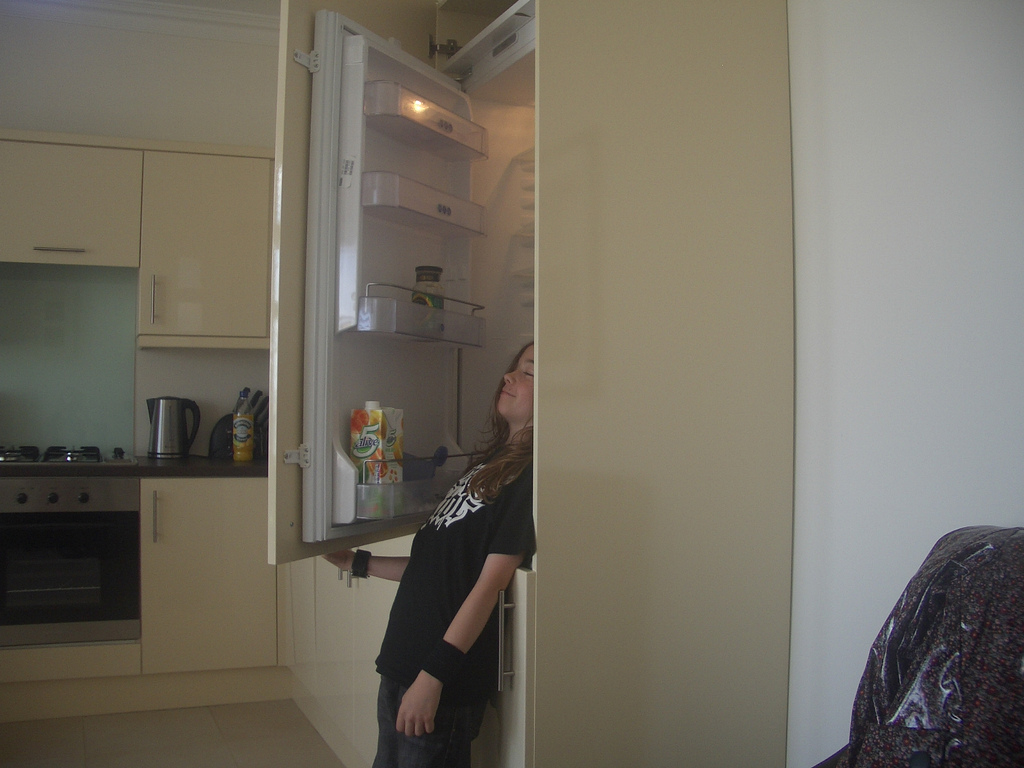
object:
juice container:
[350, 401, 405, 519]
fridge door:
[266, 0, 493, 565]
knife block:
[208, 388, 269, 462]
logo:
[421, 462, 489, 531]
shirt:
[373, 444, 535, 705]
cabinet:
[135, 149, 270, 338]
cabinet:
[0, 139, 143, 265]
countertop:
[129, 455, 268, 477]